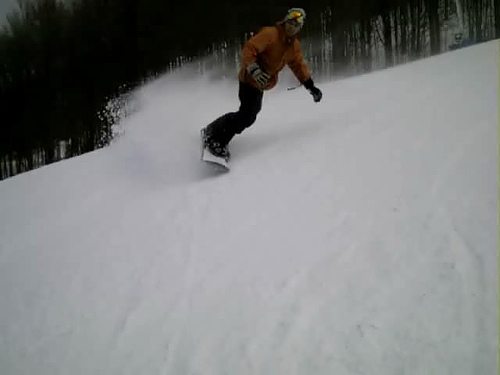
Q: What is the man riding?
A: A snowboard.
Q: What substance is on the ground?
A: Snow.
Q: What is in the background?
A: Trees.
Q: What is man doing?
A: Skiing.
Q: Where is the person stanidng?
A: Snow.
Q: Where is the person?
A: In snow.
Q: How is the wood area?
A: Large.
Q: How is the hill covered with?
A: Snow.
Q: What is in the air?
A: Snow.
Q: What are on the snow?
A: Tracks.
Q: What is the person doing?
A: Riding.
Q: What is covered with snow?
A: Hill.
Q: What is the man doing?
A: Surfing.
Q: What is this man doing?
A: Snow boarding.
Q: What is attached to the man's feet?
A: A snowboard.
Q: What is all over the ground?
A: Snow.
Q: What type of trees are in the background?
A: Dead ones.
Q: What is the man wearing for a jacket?
A: A yellow winter jacket.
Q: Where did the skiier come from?
A: Top of the trail.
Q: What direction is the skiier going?
A: Downhill.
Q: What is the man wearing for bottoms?
A: Black snow pants.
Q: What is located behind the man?
A: Treeline.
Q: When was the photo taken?
A: Day time.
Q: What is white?
A: The snow.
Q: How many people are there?
A: One.